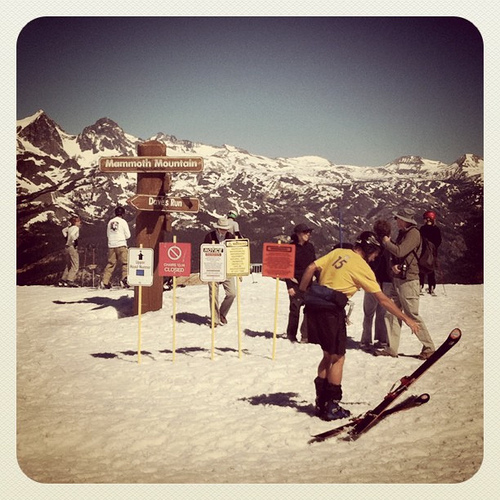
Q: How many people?
A: 10 people.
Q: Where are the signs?
A: On the mountain.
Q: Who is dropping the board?
A: The man.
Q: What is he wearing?
A: A yellow shirt.